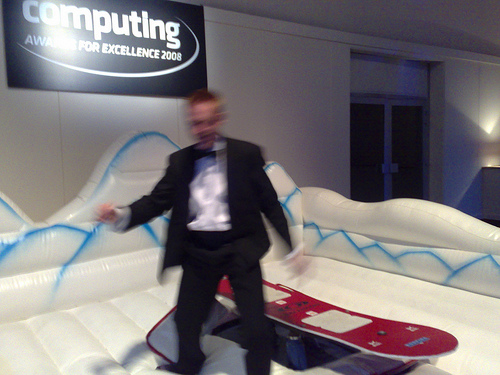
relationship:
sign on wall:
[2, 0, 209, 104] [0, 3, 497, 222]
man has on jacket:
[96, 86, 306, 374] [115, 139, 297, 283]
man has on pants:
[96, 86, 306, 374] [163, 233, 273, 374]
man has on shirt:
[96, 86, 306, 374] [183, 140, 231, 233]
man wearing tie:
[96, 86, 306, 374] [192, 146, 219, 161]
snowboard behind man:
[218, 274, 459, 361] [96, 86, 306, 374]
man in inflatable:
[96, 86, 306, 374] [2, 132, 499, 373]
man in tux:
[96, 86, 306, 374] [116, 143, 296, 374]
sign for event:
[2, 0, 209, 104] [1, 2, 494, 369]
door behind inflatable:
[352, 98, 431, 205] [2, 132, 499, 373]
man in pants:
[96, 86, 306, 374] [163, 233, 273, 374]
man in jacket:
[96, 86, 306, 374] [115, 139, 297, 283]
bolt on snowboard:
[377, 329, 386, 336] [218, 274, 459, 361]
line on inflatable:
[452, 255, 490, 278] [2, 132, 499, 373]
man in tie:
[96, 86, 306, 374] [192, 146, 219, 161]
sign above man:
[2, 0, 209, 104] [96, 86, 306, 374]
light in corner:
[483, 164, 499, 181] [483, 70, 500, 221]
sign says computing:
[2, 0, 209, 104] [23, 1, 181, 49]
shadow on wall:
[448, 107, 499, 149] [0, 3, 497, 222]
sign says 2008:
[2, 0, 209, 104] [160, 51, 184, 64]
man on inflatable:
[96, 86, 306, 374] [2, 132, 499, 373]